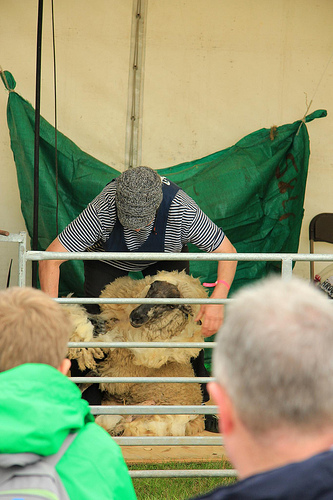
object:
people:
[0, 282, 139, 499]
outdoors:
[90, 26, 280, 154]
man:
[35, 161, 240, 343]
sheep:
[79, 268, 216, 445]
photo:
[1, 2, 329, 493]